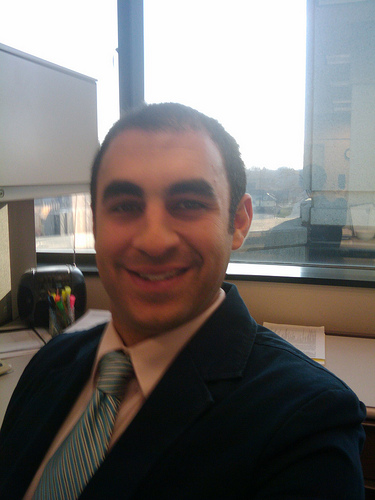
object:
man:
[0, 102, 375, 500]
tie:
[28, 349, 135, 500]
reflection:
[302, 6, 356, 277]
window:
[141, 0, 374, 270]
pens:
[49, 295, 68, 330]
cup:
[49, 301, 76, 339]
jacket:
[0, 280, 367, 500]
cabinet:
[324, 332, 374, 498]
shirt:
[21, 286, 225, 500]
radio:
[16, 195, 87, 327]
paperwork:
[262, 321, 325, 367]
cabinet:
[0, 42, 100, 203]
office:
[0, 0, 374, 500]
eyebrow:
[165, 175, 218, 202]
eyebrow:
[101, 177, 145, 205]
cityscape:
[42, 197, 88, 240]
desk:
[0, 313, 53, 433]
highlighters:
[69, 294, 75, 324]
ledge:
[35, 252, 375, 288]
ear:
[231, 192, 253, 250]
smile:
[115, 255, 199, 293]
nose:
[130, 203, 181, 261]